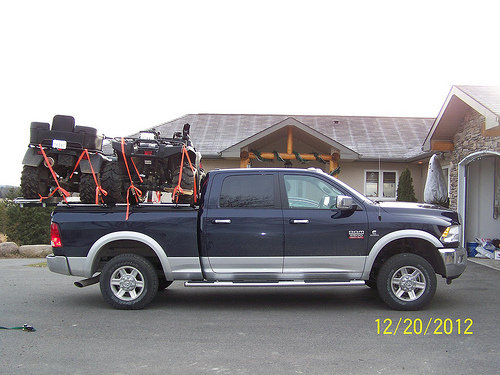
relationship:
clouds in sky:
[1, 0, 500, 133] [0, 8, 498, 186]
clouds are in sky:
[1, 0, 500, 133] [19, 43, 490, 129]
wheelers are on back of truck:
[13, 110, 202, 204] [53, 160, 469, 318]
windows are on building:
[361, 167, 408, 208] [144, 102, 498, 224]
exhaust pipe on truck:
[71, 265, 106, 290] [53, 160, 469, 318]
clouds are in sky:
[1, 0, 500, 133] [0, 10, 484, 104]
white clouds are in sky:
[2, 0, 500, 108] [0, 0, 499, 83]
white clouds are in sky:
[285, 15, 316, 48] [0, 0, 499, 83]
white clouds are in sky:
[208, 67, 273, 97] [0, 0, 499, 83]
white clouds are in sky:
[2, 0, 500, 108] [135, 12, 431, 97]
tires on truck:
[98, 251, 435, 309] [53, 160, 469, 318]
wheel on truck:
[372, 250, 439, 311] [53, 160, 469, 318]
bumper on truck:
[440, 243, 469, 283] [42, 164, 471, 310]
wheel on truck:
[372, 250, 439, 311] [42, 164, 471, 310]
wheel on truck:
[97, 251, 160, 311] [53, 160, 469, 318]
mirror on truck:
[337, 193, 355, 212] [42, 164, 471, 310]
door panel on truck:
[287, 210, 367, 275] [53, 160, 469, 318]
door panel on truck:
[206, 170, 286, 274] [60, 78, 472, 349]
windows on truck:
[361, 167, 408, 208] [53, 160, 469, 318]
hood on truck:
[376, 200, 457, 215] [42, 164, 471, 310]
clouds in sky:
[1, 0, 500, 133] [183, 1, 317, 53]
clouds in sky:
[1, 6, 488, 71] [0, 7, 500, 114]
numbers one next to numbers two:
[362, 300, 380, 345] [378, 313, 392, 334]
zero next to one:
[438, 315, 454, 339] [452, 314, 464, 339]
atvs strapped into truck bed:
[14, 113, 203, 205] [44, 200, 201, 286]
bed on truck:
[46, 202, 206, 280] [32, 125, 499, 323]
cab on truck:
[211, 168, 366, 285] [48, 154, 465, 297]